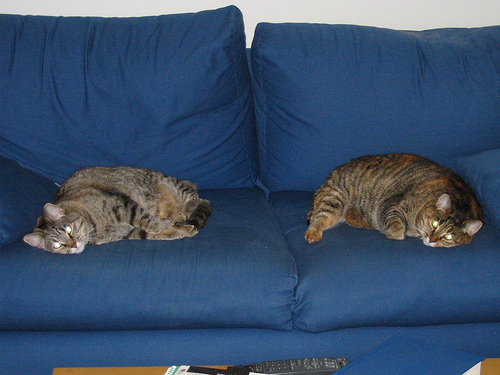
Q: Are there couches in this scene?
A: Yes, there is a couch.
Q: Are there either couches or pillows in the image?
A: Yes, there is a couch.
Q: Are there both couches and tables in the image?
A: Yes, there are both a couch and a table.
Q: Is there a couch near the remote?
A: Yes, there is a couch near the remote.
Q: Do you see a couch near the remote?
A: Yes, there is a couch near the remote.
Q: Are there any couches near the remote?
A: Yes, there is a couch near the remote.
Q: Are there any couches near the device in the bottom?
A: Yes, there is a couch near the remote.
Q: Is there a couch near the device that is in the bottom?
A: Yes, there is a couch near the remote.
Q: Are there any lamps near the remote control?
A: No, there is a couch near the remote control.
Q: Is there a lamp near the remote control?
A: No, there is a couch near the remote control.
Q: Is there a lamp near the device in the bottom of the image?
A: No, there is a couch near the remote control.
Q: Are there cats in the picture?
A: Yes, there is a cat.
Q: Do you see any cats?
A: Yes, there is a cat.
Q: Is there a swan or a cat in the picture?
A: Yes, there is a cat.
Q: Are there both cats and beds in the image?
A: No, there is a cat but no beds.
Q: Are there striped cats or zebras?
A: Yes, there is a striped cat.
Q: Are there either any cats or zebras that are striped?
A: Yes, the cat is striped.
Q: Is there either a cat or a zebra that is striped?
A: Yes, the cat is striped.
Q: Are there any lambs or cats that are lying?
A: Yes, the cat is lying.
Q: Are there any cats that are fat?
A: Yes, there is a fat cat.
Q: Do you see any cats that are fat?
A: Yes, there is a cat that is fat.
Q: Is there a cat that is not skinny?
A: Yes, there is a fat cat.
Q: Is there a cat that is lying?
A: Yes, there is a cat that is lying.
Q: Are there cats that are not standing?
A: Yes, there is a cat that is lying.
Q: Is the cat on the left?
A: Yes, the cat is on the left of the image.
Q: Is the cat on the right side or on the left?
A: The cat is on the left of the image.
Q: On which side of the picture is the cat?
A: The cat is on the left of the image.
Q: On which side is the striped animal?
A: The cat is on the left of the image.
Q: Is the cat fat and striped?
A: Yes, the cat is fat and striped.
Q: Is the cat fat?
A: Yes, the cat is fat.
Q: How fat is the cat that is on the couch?
A: The cat is fat.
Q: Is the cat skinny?
A: No, the cat is fat.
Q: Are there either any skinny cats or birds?
A: No, there is a cat but it is fat.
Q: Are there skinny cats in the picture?
A: No, there is a cat but it is fat.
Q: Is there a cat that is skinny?
A: No, there is a cat but it is fat.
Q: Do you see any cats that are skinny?
A: No, there is a cat but it is fat.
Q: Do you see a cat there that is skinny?
A: No, there is a cat but it is fat.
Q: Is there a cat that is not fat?
A: No, there is a cat but it is fat.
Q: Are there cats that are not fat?
A: No, there is a cat but it is fat.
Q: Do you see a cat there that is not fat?
A: No, there is a cat but it is fat.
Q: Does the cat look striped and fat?
A: Yes, the cat is striped and fat.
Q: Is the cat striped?
A: Yes, the cat is striped.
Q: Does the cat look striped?
A: Yes, the cat is striped.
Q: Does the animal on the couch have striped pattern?
A: Yes, the cat is striped.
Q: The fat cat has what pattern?
A: The cat is striped.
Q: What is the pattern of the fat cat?
A: The cat is striped.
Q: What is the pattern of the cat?
A: The cat is striped.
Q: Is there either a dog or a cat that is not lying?
A: No, there is a cat but it is lying.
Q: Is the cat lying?
A: Yes, the cat is lying.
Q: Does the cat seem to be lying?
A: Yes, the cat is lying.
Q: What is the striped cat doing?
A: The cat is lying.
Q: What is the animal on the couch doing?
A: The cat is lying.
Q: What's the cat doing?
A: The cat is lying.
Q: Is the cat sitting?
A: No, the cat is lying.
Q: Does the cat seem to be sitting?
A: No, the cat is lying.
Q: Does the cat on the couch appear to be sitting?
A: No, the cat is lying.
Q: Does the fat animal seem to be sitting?
A: No, the cat is lying.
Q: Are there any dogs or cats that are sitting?
A: No, there is a cat but it is lying.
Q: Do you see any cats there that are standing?
A: No, there is a cat but it is lying.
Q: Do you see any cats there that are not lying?
A: No, there is a cat but it is lying.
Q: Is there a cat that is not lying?
A: No, there is a cat but it is lying.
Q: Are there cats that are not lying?
A: No, there is a cat but it is lying.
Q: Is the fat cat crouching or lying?
A: The cat is lying.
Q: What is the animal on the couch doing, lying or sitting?
A: The cat is lying.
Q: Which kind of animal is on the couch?
A: The animal is a cat.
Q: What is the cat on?
A: The cat is on the couch.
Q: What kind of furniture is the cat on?
A: The cat is on the couch.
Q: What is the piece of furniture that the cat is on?
A: The piece of furniture is a couch.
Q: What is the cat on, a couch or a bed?
A: The cat is on a couch.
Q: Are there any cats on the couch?
A: Yes, there is a cat on the couch.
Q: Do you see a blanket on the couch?
A: No, there is a cat on the couch.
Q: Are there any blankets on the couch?
A: No, there is a cat on the couch.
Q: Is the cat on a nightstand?
A: No, the cat is on the couch.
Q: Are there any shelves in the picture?
A: No, there are no shelves.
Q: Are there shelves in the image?
A: No, there are no shelves.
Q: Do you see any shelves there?
A: No, there are no shelves.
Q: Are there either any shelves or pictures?
A: No, there are no shelves or pictures.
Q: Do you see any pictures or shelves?
A: No, there are no shelves or pictures.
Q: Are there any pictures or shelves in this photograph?
A: No, there are no shelves or pictures.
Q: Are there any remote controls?
A: Yes, there is a remote control.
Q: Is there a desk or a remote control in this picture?
A: Yes, there is a remote control.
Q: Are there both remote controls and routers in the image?
A: No, there is a remote control but no routers.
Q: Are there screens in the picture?
A: No, there are no screens.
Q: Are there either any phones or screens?
A: No, there are no screens or phones.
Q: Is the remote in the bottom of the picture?
A: Yes, the remote is in the bottom of the image.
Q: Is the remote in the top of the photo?
A: No, the remote is in the bottom of the image.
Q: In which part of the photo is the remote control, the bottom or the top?
A: The remote control is in the bottom of the image.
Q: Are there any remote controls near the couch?
A: Yes, there is a remote control near the couch.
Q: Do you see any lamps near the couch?
A: No, there is a remote control near the couch.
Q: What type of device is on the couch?
A: The device is a remote control.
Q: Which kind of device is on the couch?
A: The device is a remote control.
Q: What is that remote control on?
A: The remote control is on the couch.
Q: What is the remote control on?
A: The remote control is on the couch.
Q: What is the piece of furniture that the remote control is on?
A: The piece of furniture is a couch.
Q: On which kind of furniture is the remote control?
A: The remote control is on the couch.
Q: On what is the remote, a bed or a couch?
A: The remote is on a couch.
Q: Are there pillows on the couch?
A: No, there is a remote control on the couch.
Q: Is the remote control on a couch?
A: Yes, the remote control is on a couch.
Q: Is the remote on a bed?
A: No, the remote is on a couch.